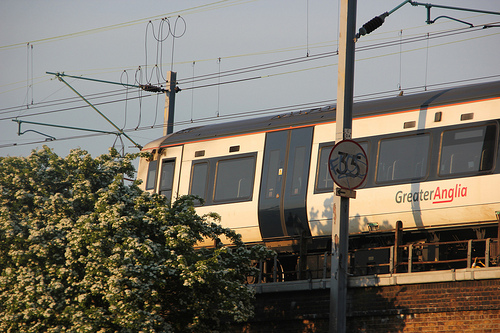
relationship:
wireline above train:
[0, 9, 498, 157] [127, 74, 499, 255]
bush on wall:
[2, 149, 277, 331] [244, 278, 500, 328]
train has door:
[127, 74, 499, 255] [257, 123, 313, 243]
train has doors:
[127, 74, 499, 255] [257, 123, 313, 243]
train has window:
[127, 74, 499, 255] [183, 112, 498, 205]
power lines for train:
[7, 8, 476, 145] [138, 81, 479, 267]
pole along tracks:
[328, 5, 362, 333] [218, 236, 481, 286]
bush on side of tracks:
[0, 146, 277, 332] [211, 240, 483, 279]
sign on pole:
[390, 184, 473, 206] [332, 5, 356, 331]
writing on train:
[392, 181, 472, 205] [127, 74, 499, 255]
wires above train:
[6, 7, 481, 143] [138, 81, 479, 267]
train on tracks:
[127, 74, 499, 255] [221, 242, 484, 309]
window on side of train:
[182, 151, 253, 201] [127, 74, 499, 255]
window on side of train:
[316, 122, 484, 181] [127, 74, 499, 255]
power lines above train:
[7, 8, 476, 145] [138, 81, 479, 267]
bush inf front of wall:
[2, 149, 277, 331] [228, 264, 496, 329]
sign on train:
[390, 184, 473, 206] [133, 91, 496, 261]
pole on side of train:
[328, 5, 362, 333] [107, 73, 481, 308]